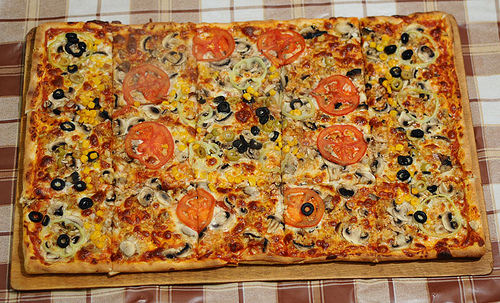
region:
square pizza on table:
[31, 11, 499, 301]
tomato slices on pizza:
[111, 16, 376, 248]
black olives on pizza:
[196, 82, 285, 157]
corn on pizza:
[78, 45, 118, 230]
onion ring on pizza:
[225, 37, 274, 107]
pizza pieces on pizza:
[314, 140, 378, 203]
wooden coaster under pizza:
[8, 0, 498, 302]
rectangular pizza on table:
[14, 3, 481, 255]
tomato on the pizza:
[312, 121, 369, 170]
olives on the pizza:
[68, 170, 103, 216]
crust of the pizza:
[45, 242, 195, 292]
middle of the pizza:
[199, 92, 301, 167]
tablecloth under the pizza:
[243, 268, 396, 301]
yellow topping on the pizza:
[73, 128, 104, 193]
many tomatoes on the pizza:
[74, 25, 412, 256]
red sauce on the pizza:
[427, 49, 454, 94]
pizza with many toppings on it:
[10, 13, 473, 301]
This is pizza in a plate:
[20, 10, 497, 285]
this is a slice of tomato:
[273, 183, 330, 228]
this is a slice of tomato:
[303, 120, 372, 171]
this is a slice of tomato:
[309, 71, 369, 117]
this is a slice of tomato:
[122, 118, 182, 171]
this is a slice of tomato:
[165, 186, 239, 240]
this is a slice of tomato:
[105, 63, 193, 114]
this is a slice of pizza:
[374, 168, 494, 255]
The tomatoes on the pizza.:
[125, 24, 370, 229]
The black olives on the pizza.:
[53, 33, 459, 233]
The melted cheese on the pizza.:
[40, 25, 470, 250]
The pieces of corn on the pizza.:
[50, 30, 460, 250]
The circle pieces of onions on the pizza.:
[40, 27, 461, 247]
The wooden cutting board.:
[12, 15, 487, 290]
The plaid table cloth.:
[2, 1, 497, 296]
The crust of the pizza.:
[15, 12, 486, 266]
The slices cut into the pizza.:
[40, 23, 475, 262]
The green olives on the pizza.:
[50, 41, 470, 251]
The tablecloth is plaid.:
[5, 2, 492, 301]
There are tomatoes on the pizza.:
[112, 62, 212, 177]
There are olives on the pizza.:
[50, 36, 99, 93]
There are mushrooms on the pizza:
[339, 226, 426, 248]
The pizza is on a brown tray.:
[14, 20, 491, 286]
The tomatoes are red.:
[173, 175, 355, 226]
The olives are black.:
[22, 196, 93, 253]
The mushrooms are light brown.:
[394, 200, 471, 235]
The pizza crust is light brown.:
[22, 254, 235, 273]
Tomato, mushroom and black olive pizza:
[12, 7, 490, 286]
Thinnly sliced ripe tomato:
[120, 122, 175, 171]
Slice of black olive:
[61, 34, 86, 57]